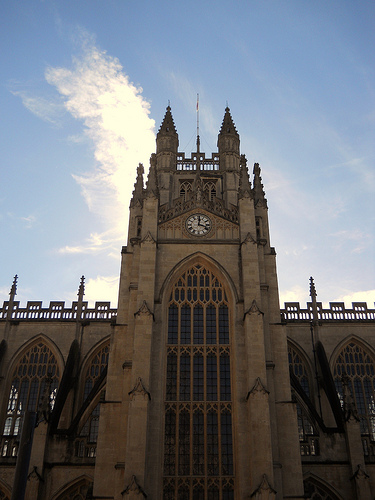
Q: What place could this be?
A: It is a city.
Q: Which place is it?
A: It is a city.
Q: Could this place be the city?
A: Yes, it is the city.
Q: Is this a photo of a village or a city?
A: It is showing a city.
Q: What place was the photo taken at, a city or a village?
A: It was taken at a city.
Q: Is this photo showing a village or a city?
A: It is showing a city.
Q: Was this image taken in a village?
A: No, the picture was taken in a city.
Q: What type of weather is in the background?
A: It is clear.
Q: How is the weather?
A: It is clear.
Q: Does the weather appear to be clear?
A: Yes, it is clear.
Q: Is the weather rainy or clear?
A: It is clear.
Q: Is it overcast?
A: No, it is clear.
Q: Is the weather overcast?
A: No, it is clear.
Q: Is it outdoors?
A: Yes, it is outdoors.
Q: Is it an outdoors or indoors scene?
A: It is outdoors.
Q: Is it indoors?
A: No, it is outdoors.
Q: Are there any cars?
A: No, there are no cars.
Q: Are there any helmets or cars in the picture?
A: No, there are no cars or helmets.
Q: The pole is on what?
A: The pole is on the building.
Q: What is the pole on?
A: The pole is on the building.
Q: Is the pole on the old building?
A: Yes, the pole is on the building.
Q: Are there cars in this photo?
A: No, there are no cars.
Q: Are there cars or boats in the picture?
A: No, there are no cars or boats.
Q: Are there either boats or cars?
A: No, there are no cars or boats.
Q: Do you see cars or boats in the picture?
A: No, there are no cars or boats.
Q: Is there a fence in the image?
A: No, there are no fences.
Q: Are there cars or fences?
A: No, there are no fences or cars.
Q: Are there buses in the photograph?
A: No, there are no buses.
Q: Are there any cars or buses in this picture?
A: No, there are no buses or cars.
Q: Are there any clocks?
A: Yes, there is a clock.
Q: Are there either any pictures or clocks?
A: Yes, there is a clock.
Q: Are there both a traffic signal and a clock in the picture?
A: No, there is a clock but no traffic lights.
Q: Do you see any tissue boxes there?
A: No, there are no tissue boxes.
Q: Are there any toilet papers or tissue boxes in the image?
A: No, there are no tissue boxes or toilet papers.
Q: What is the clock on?
A: The clock is on the building.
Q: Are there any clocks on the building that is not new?
A: Yes, there is a clock on the building.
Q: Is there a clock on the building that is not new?
A: Yes, there is a clock on the building.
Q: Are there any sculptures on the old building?
A: No, there is a clock on the building.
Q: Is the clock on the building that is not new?
A: Yes, the clock is on the building.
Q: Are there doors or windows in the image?
A: Yes, there are windows.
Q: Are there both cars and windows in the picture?
A: No, there are windows but no cars.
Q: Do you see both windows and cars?
A: No, there are windows but no cars.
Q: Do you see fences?
A: No, there are no fences.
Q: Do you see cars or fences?
A: No, there are no fences or cars.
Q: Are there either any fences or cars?
A: No, there are no fences or cars.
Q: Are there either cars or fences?
A: No, there are no fences or cars.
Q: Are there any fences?
A: No, there are no fences.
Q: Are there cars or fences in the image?
A: No, there are no fences or cars.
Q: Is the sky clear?
A: Yes, the sky is clear.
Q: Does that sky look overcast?
A: No, the sky is clear.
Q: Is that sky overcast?
A: No, the sky is clear.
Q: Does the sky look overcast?
A: No, the sky is clear.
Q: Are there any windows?
A: Yes, there is a window.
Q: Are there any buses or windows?
A: Yes, there is a window.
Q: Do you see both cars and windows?
A: No, there is a window but no cars.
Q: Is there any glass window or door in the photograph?
A: Yes, there is a glass window.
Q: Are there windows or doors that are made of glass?
A: Yes, the window is made of glass.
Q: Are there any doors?
A: No, there are no doors.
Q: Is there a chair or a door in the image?
A: No, there are no doors or chairs.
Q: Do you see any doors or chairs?
A: No, there are no doors or chairs.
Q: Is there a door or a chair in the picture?
A: No, there are no doors or chairs.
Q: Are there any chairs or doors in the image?
A: No, there are no doors or chairs.